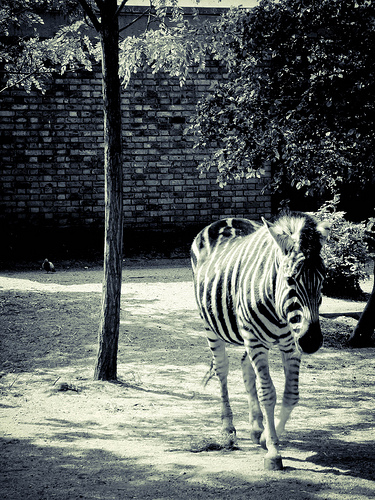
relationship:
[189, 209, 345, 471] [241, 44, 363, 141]
animal standing in forest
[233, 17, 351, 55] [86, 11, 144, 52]
trees with branches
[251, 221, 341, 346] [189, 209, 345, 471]
head of animal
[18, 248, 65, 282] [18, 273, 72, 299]
bird in dirt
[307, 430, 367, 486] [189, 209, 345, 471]
shadow of animal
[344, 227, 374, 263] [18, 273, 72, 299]
plants and leaves in dirt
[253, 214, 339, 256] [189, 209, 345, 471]
ears of animal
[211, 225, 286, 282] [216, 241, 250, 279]
black and white color lines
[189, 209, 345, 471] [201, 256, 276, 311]
animal has black stripes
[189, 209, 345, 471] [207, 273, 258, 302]
animal has white stripes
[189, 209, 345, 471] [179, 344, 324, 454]
animal has four legs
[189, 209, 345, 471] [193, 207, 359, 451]
animal has hoofs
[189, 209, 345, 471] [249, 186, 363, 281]
animal has two ears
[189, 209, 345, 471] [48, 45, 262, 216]
animal inside pen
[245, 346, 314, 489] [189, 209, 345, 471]
front legs of animal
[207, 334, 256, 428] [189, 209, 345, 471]
back legs of animal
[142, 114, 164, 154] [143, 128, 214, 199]
wall of brick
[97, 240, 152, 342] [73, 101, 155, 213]
trunk of tree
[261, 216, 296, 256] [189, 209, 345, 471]
ears of animal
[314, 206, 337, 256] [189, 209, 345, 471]
left ear of animal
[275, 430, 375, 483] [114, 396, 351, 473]
shadow on ground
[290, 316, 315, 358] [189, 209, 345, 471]
muzzle of animal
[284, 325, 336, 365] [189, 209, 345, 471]
nostrils of animal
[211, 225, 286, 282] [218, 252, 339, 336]
black and white of animal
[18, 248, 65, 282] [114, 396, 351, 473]
pigeon on ground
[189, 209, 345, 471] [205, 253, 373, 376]
animal making way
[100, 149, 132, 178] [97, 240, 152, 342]
thin tree trunk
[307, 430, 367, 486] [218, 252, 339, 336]
shadow of animal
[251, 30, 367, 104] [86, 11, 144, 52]
leaves and branches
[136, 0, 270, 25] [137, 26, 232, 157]
top ledge of brick wall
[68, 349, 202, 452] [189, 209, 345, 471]
dirt field where animal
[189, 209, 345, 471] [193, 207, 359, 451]
animal in zoo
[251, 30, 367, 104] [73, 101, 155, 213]
leaves on tree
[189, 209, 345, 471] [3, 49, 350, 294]
animal in zoo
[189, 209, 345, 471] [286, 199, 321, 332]
animal with head up